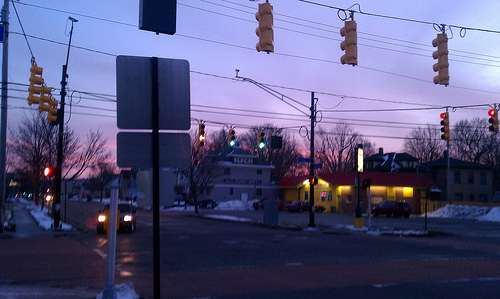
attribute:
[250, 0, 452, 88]
street lights — in a row, hanging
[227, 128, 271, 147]
lights — green, turned green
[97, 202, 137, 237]
car — making a turn, turning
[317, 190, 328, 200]
sign — lit up, lighted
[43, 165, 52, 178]
hand signal — red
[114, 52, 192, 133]
back of street sign — rectangular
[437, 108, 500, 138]
street lights — red, turned red, facing street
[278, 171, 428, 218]
building — yellow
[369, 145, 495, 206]
victorian house — large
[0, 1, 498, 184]
sky — pink, pinkish red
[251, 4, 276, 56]
street light — hanging from wire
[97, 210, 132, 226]
car headlights — on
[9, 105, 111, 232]
trees — bare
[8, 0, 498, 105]
wires — overhead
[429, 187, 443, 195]
street sign — blue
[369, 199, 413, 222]
car — maroon colored, parked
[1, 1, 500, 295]
scene — dusk looking